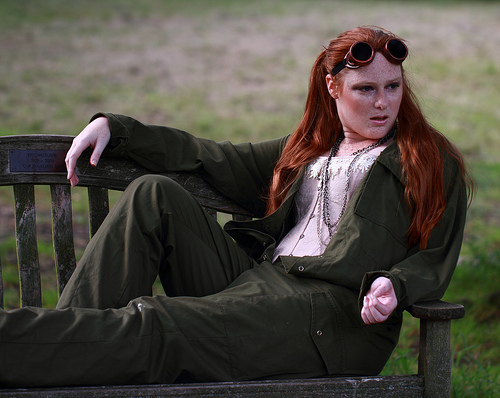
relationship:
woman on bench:
[2, 27, 468, 390] [2, 131, 468, 396]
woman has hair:
[2, 27, 468, 390] [259, 26, 475, 252]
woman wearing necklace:
[2, 27, 468, 390] [321, 125, 398, 242]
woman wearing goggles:
[2, 27, 468, 390] [332, 37, 409, 74]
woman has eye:
[2, 27, 468, 390] [385, 82, 401, 93]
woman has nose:
[2, 27, 468, 390] [373, 88, 391, 112]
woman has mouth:
[2, 27, 468, 390] [368, 112, 391, 126]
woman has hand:
[2, 27, 468, 390] [61, 115, 111, 187]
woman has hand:
[2, 27, 468, 390] [359, 275, 398, 325]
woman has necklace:
[2, 27, 468, 390] [321, 125, 398, 242]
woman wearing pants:
[2, 27, 468, 390] [1, 173, 401, 387]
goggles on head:
[332, 37, 409, 74] [324, 25, 409, 142]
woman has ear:
[2, 27, 468, 390] [324, 72, 339, 100]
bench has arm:
[2, 131, 468, 396] [402, 295, 468, 397]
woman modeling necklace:
[2, 27, 468, 390] [321, 125, 398, 242]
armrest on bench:
[402, 295, 468, 397] [2, 131, 468, 396]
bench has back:
[2, 131, 468, 396] [1, 134, 265, 316]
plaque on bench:
[7, 144, 66, 176] [2, 131, 468, 396]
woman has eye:
[2, 27, 468, 390] [354, 84, 376, 95]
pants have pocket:
[1, 173, 401, 387] [218, 289, 347, 379]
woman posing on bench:
[2, 27, 468, 390] [2, 131, 468, 396]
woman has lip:
[2, 27, 468, 390] [371, 113, 391, 119]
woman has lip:
[2, 27, 468, 390] [370, 118, 389, 125]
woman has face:
[2, 27, 468, 390] [334, 53, 407, 140]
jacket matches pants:
[87, 112, 470, 379] [1, 173, 401, 387]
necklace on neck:
[321, 125, 398, 242] [342, 126, 369, 145]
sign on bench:
[7, 144, 66, 176] [2, 131, 468, 396]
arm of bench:
[402, 295, 468, 397] [2, 131, 468, 396]